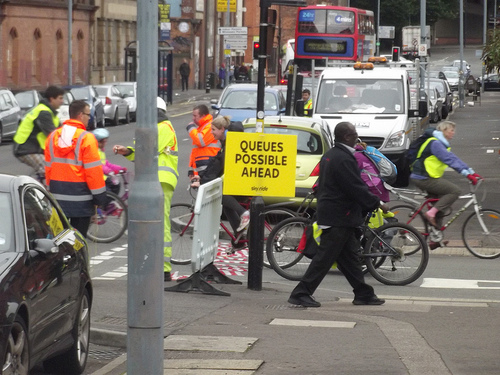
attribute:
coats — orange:
[51, 126, 231, 192]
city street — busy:
[1, 79, 466, 307]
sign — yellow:
[225, 133, 292, 194]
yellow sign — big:
[220, 130, 297, 197]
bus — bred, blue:
[282, 7, 414, 81]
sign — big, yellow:
[227, 130, 308, 193]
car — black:
[5, 171, 98, 348]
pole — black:
[253, 199, 272, 303]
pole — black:
[245, 203, 267, 291]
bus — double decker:
[293, 3, 378, 65]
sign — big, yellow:
[222, 129, 297, 197]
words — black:
[234, 139, 287, 191]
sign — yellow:
[223, 125, 288, 210]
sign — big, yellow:
[147, 126, 348, 214]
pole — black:
[244, 10, 278, 72]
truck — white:
[304, 60, 421, 177]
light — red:
[254, 41, 260, 59]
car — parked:
[0, 85, 23, 145]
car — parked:
[10, 83, 44, 124]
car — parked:
[88, 79, 130, 126]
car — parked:
[108, 77, 136, 117]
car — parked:
[4, 171, 118, 352]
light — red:
[390, 44, 403, 71]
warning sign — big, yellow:
[222, 129, 298, 212]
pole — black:
[244, 199, 263, 289]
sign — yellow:
[228, 131, 295, 201]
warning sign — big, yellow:
[219, 127, 308, 208]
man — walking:
[286, 118, 393, 308]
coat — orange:
[43, 125, 93, 200]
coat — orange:
[39, 116, 105, 191]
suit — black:
[296, 136, 381, 299]